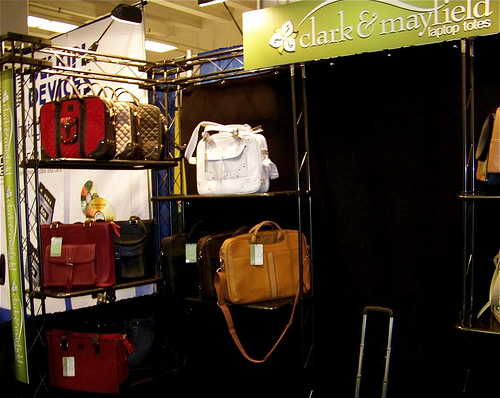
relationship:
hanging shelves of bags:
[6, 28, 322, 395] [36, 81, 165, 161]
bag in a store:
[212, 220, 312, 364] [10, 9, 498, 386]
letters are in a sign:
[296, 2, 493, 52] [240, 1, 487, 97]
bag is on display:
[183, 120, 280, 196] [6, 29, 322, 396]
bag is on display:
[212, 220, 312, 364] [6, 29, 322, 396]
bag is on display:
[46, 328, 136, 396] [6, 29, 322, 396]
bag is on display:
[38, 220, 120, 290] [6, 29, 322, 396]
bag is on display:
[41, 78, 116, 159] [6, 29, 322, 396]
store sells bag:
[10, 9, 498, 386] [210, 218, 312, 363]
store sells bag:
[10, 9, 498, 386] [183, 120, 280, 197]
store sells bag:
[10, 9, 498, 386] [38, 220, 120, 287]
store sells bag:
[10, 9, 498, 386] [41, 77, 115, 157]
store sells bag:
[10, 9, 498, 386] [113, 84, 163, 157]